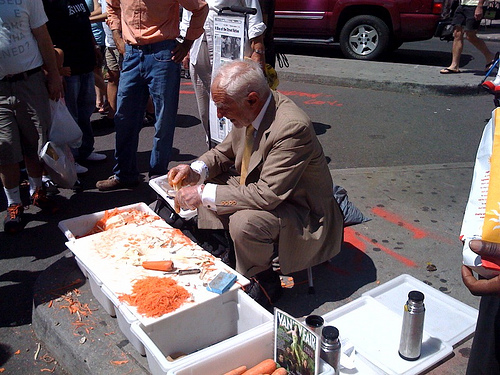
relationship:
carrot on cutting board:
[131, 275, 188, 316] [64, 219, 248, 323]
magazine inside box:
[270, 307, 318, 371] [171, 321, 337, 375]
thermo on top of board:
[397, 286, 426, 364] [312, 273, 481, 375]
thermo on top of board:
[319, 321, 342, 372] [312, 273, 481, 375]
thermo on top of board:
[309, 313, 322, 324] [312, 273, 481, 375]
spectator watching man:
[99, 3, 211, 190] [165, 57, 339, 298]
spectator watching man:
[46, 2, 99, 180] [165, 57, 339, 298]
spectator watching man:
[0, 1, 63, 227] [165, 57, 339, 298]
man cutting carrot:
[165, 57, 339, 298] [131, 275, 188, 316]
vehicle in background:
[264, 2, 444, 57] [268, 2, 494, 139]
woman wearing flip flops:
[439, 0, 497, 79] [439, 64, 461, 74]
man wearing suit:
[165, 57, 339, 298] [194, 90, 343, 286]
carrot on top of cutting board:
[131, 275, 188, 316] [64, 219, 248, 323]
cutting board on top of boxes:
[64, 219, 248, 323] [55, 198, 284, 375]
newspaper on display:
[206, 16, 246, 148] [207, 14, 246, 145]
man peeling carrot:
[165, 57, 339, 298] [131, 275, 188, 316]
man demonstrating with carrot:
[165, 57, 339, 298] [131, 275, 188, 316]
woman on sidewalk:
[439, 0, 497, 79] [272, 52, 499, 88]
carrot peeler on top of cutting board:
[167, 268, 201, 276] [64, 219, 248, 323]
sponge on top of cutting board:
[207, 271, 235, 296] [64, 219, 248, 323]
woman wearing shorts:
[439, 0, 497, 79] [447, 3, 485, 31]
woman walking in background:
[439, 0, 497, 79] [268, 2, 494, 139]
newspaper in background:
[206, 16, 246, 148] [268, 2, 494, 139]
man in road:
[165, 57, 339, 298] [0, 76, 491, 366]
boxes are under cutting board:
[55, 198, 284, 375] [64, 219, 248, 323]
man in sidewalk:
[165, 57, 339, 298] [28, 157, 495, 374]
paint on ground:
[372, 205, 427, 243] [0, 69, 490, 372]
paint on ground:
[178, 81, 339, 104] [0, 69, 490, 372]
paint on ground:
[326, 223, 413, 283] [0, 69, 490, 372]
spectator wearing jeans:
[99, 3, 211, 190] [114, 35, 181, 178]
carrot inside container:
[243, 353, 280, 374] [171, 321, 337, 375]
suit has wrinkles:
[194, 90, 343, 286] [220, 145, 301, 215]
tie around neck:
[238, 123, 255, 186] [239, 95, 275, 134]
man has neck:
[165, 57, 339, 298] [239, 95, 275, 134]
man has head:
[165, 57, 339, 298] [212, 56, 270, 134]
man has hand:
[165, 57, 339, 298] [176, 182, 208, 216]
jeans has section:
[114, 35, 181, 178] [132, 60, 164, 80]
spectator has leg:
[99, 3, 211, 190] [112, 53, 152, 185]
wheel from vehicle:
[337, 8, 396, 62] [264, 2, 444, 57]